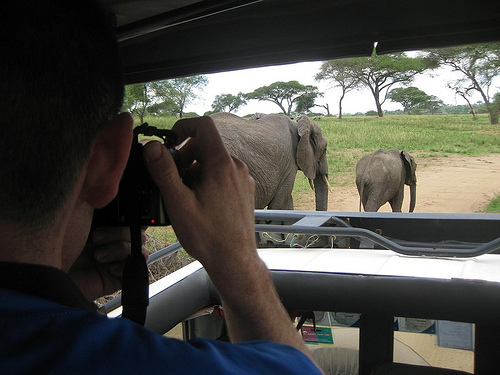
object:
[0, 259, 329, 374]
shirt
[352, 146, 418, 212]
elephant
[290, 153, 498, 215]
dirt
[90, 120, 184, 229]
camera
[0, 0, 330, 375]
person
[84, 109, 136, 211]
ear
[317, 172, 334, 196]
horns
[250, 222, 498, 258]
bar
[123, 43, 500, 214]
window